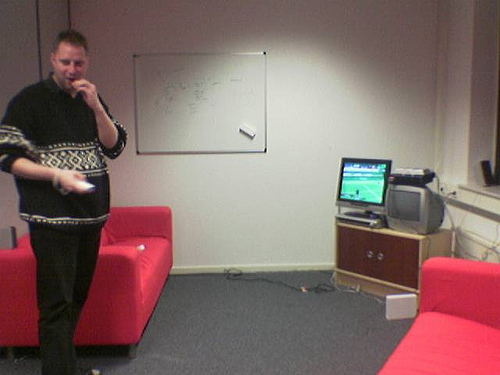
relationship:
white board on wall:
[130, 51, 265, 153] [1, 0, 439, 272]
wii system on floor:
[383, 293, 418, 322] [1, 273, 419, 372]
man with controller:
[1, 29, 129, 372] [73, 179, 95, 191]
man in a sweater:
[1, 29, 129, 372] [0, 77, 126, 227]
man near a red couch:
[1, 29, 129, 372] [0, 206, 172, 344]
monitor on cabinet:
[336, 156, 392, 211] [334, 218, 452, 304]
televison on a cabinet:
[385, 185, 448, 232] [334, 218, 452, 304]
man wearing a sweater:
[1, 29, 129, 372] [0, 77, 126, 227]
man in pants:
[1, 29, 129, 372] [27, 223, 104, 375]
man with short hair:
[1, 29, 129, 372] [52, 29, 89, 61]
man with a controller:
[1, 29, 129, 372] [73, 179, 95, 191]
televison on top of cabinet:
[385, 185, 448, 232] [334, 218, 452, 304]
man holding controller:
[1, 29, 129, 372] [73, 179, 95, 191]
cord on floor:
[226, 266, 334, 291] [1, 273, 419, 372]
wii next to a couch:
[383, 293, 418, 322] [375, 256, 499, 373]